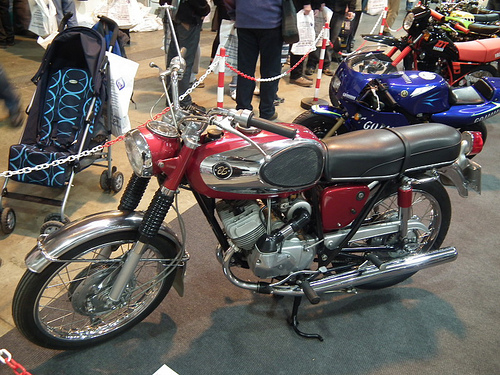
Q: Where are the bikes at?
A: A bike show.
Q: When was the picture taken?
A: Daytime.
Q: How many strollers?
A: One.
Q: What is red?
A: Bike in front.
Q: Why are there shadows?
A: Light is shining on the bikes.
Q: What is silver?
A: Chrome on the bikes.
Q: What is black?
A: Tires.